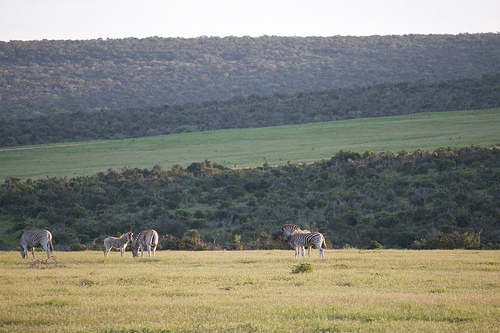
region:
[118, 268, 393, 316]
the grass is brown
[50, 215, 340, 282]
there are five zebras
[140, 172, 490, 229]
the trees are green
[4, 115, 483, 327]
the photo was taken in the wild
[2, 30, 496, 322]
its daytime in the photo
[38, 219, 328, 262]
the strips are black and white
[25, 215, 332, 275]
the zebras are grazing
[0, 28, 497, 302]
photo was taken in africa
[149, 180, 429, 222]
the forest are thick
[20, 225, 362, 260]
the zebras are together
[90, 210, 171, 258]
wild animals in field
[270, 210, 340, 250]
zebra having fun outside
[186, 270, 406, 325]
meadow near other bushes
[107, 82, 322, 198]
grassy landscape in nature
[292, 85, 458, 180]
hilly area outside in nature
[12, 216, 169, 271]
animals feeding in the grass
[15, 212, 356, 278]
animals together in nature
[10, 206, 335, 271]
animals in a field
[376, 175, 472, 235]
plants and bushes outside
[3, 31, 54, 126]
hilly outdoor landscape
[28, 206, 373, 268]
zebras in the field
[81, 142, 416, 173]
the grass is green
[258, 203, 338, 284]
the zebras are stripes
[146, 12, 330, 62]
the sky is white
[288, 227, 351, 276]
the zebra's stripes are black and white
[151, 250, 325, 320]
the ground has grass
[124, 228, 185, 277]
a zebra is eating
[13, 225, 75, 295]
the zebra is eating grass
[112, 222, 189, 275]
the zebra's butt is brown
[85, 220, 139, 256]
the zebra is facing left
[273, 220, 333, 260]
Zebra standing in grass field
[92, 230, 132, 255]
Zebra standing in grass field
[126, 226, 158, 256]
Zebra grazing on grass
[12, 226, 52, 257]
Zebra grazing on grass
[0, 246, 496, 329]
Grass field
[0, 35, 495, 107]
Hill in the background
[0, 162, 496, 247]
Shrubs and trees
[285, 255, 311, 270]
Small shrub in middle of grass field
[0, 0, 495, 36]
Blue sky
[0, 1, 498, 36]
Clear sky with no clouds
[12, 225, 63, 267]
Lone zebra on the end closest to the middle group of zebras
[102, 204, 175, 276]
Two zebras in the middle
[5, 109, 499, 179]
Lightest green strip of land that is sloping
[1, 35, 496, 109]
Dark green trees above the slanted line of trees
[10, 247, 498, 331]
Grass the zebras are standing on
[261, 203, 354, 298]
Two zebras on the end of the zebras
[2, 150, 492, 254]
Dark trees closest to the zebras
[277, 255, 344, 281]
Bush in front of two zebras on the end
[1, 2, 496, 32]
Sky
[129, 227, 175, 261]
Zebra that is eating in the middle group of zebras